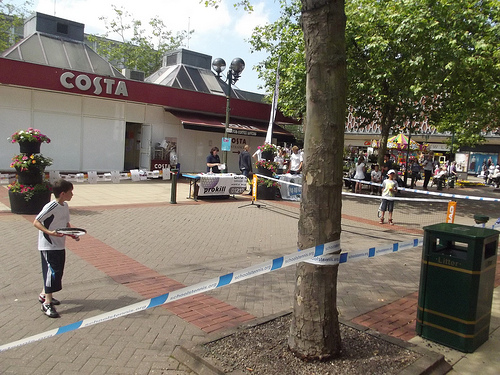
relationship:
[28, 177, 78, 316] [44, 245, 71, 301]
boy wearing black shorts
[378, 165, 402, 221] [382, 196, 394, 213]
boy wearing black shorts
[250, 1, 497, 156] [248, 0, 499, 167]
leaves on tree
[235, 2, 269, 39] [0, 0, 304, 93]
clouds in sky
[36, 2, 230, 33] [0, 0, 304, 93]
clouds in sky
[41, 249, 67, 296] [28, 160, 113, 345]
black shorts on boy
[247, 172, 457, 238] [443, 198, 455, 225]
net on support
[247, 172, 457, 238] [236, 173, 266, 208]
net on support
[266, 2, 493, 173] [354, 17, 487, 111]
tree has leaves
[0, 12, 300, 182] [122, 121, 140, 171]
restaurant has entry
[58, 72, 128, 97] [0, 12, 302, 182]
sign is on building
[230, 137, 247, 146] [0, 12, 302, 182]
sign is on building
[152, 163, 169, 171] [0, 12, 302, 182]
sign is on building